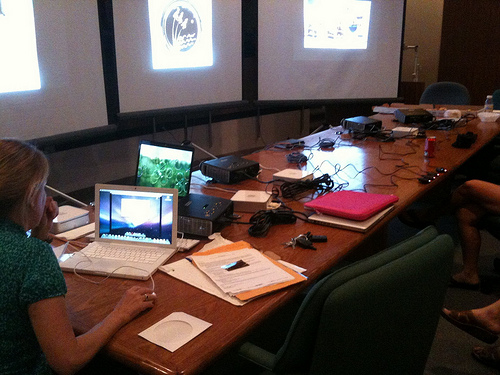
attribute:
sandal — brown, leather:
[440, 303, 500, 346]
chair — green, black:
[240, 225, 453, 375]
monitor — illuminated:
[96, 190, 176, 247]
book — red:
[302, 190, 399, 230]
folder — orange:
[195, 239, 306, 302]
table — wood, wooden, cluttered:
[36, 99, 496, 372]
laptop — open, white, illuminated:
[61, 180, 177, 279]